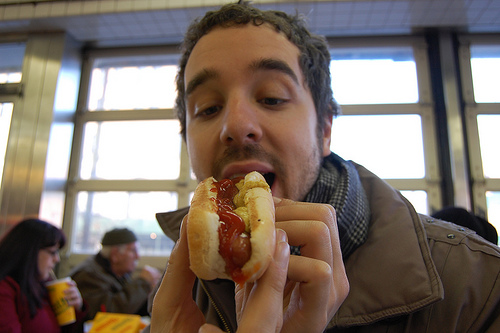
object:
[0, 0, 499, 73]
roof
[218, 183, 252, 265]
hotdog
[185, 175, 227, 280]
bun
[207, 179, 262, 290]
ketchup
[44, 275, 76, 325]
cup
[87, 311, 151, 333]
box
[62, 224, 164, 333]
man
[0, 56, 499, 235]
sky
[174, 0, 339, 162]
hair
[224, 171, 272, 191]
eat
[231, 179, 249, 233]
mustard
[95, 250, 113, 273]
collar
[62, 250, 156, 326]
coat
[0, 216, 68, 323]
hair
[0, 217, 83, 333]
woman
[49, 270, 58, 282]
straw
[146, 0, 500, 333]
guy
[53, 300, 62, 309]
letters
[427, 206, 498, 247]
hat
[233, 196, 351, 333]
hands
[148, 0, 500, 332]
man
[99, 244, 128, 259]
hair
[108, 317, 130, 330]
writing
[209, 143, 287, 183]
mustache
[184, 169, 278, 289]
food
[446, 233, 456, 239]
rivets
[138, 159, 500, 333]
coat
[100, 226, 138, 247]
cap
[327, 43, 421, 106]
window